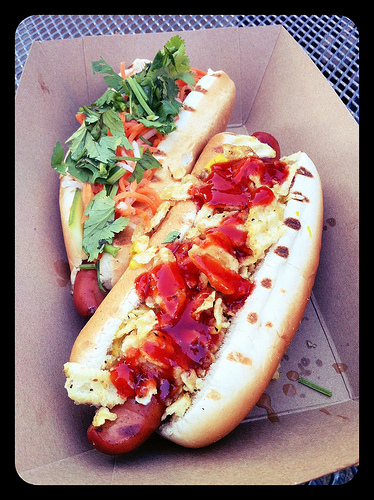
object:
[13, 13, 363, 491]
table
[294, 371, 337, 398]
herb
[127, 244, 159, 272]
mustard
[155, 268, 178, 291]
sauce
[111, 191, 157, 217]
tomato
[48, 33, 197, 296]
cilantro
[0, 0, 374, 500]
photo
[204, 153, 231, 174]
mustard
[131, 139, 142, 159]
onion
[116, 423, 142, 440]
grill mark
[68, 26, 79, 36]
holes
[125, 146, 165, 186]
leafy greens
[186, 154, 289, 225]
ketchup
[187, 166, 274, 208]
tomato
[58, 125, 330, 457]
hot dog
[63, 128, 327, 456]
bread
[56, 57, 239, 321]
hot dog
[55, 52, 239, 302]
bun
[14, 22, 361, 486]
tray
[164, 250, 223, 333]
topping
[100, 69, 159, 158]
topping